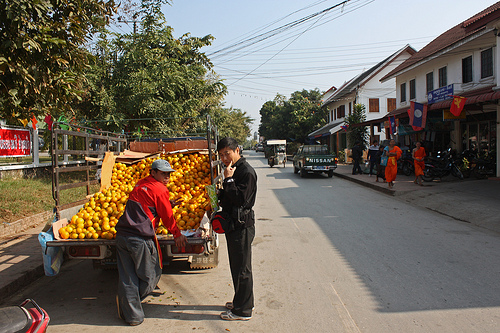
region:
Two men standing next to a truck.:
[105, 135, 257, 323]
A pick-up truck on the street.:
[285, 130, 337, 185]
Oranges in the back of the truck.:
[37, 150, 207, 235]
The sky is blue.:
[185, 6, 280, 22]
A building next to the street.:
[376, 10, 493, 181]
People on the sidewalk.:
[350, 128, 471, 193]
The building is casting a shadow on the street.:
[275, 180, 496, 313]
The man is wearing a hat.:
[141, 145, 181, 190]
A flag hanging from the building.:
[405, 96, 430, 136]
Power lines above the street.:
[205, 6, 439, 69]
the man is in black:
[218, 165, 258, 314]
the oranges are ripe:
[106, 168, 126, 208]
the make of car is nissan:
[282, 140, 342, 185]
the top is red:
[114, 170, 183, 240]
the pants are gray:
[110, 238, 171, 322]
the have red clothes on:
[375, 140, 431, 182]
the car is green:
[290, 145, 337, 178]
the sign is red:
[1, 130, 42, 160]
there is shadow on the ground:
[313, 195, 416, 305]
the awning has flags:
[400, 94, 485, 109]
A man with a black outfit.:
[212, 136, 262, 323]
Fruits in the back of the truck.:
[61, 145, 214, 238]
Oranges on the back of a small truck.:
[56, 136, 217, 237]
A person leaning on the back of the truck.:
[119, 152, 183, 332]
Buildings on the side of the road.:
[314, 4, 493, 169]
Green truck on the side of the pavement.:
[292, 140, 340, 178]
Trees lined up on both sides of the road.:
[0, 2, 322, 219]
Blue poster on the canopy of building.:
[427, 82, 458, 105]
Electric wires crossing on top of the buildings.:
[207, 0, 400, 93]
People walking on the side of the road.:
[380, 136, 435, 188]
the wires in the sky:
[226, 4, 362, 76]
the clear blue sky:
[191, 0, 263, 24]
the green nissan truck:
[295, 144, 335, 173]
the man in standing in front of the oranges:
[121, 160, 183, 322]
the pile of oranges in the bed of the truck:
[81, 152, 208, 230]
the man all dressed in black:
[213, 137, 255, 319]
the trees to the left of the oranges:
[7, 3, 203, 121]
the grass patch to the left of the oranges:
[6, 175, 47, 207]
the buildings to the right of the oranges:
[322, 3, 497, 203]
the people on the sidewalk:
[348, 137, 429, 189]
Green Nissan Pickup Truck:
[292, 143, 339, 173]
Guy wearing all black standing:
[212, 136, 260, 322]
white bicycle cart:
[263, 136, 288, 169]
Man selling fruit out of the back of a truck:
[117, 157, 187, 325]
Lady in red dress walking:
[411, 137, 430, 190]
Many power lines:
[259, 2, 359, 28]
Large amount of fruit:
[178, 159, 207, 214]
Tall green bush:
[347, 101, 368, 176]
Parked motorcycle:
[422, 145, 470, 185]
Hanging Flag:
[407, 98, 429, 130]